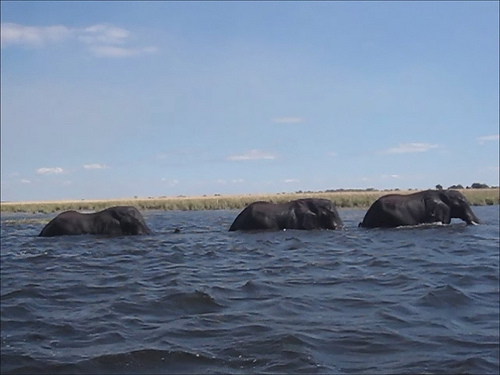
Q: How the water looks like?
A: Blue.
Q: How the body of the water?
A: Choppy blue.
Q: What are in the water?
A: Elephants.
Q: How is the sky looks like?
A: Blue sky.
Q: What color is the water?
A: Blue.